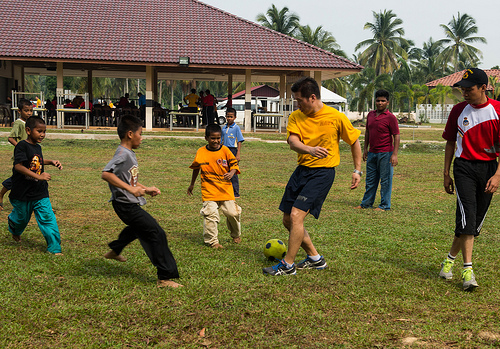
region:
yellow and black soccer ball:
[261, 235, 286, 265]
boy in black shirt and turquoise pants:
[11, 117, 70, 259]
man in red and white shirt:
[440, 68, 496, 298]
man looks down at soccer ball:
[434, 66, 498, 293]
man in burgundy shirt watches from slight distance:
[361, 89, 406, 211]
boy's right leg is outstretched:
[102, 109, 184, 290]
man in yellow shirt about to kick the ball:
[258, 70, 367, 283]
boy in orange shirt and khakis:
[191, 123, 246, 248]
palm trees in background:
[253, 4, 488, 111]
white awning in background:
[319, 81, 351, 106]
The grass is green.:
[241, 291, 282, 343]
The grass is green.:
[224, 265, 348, 345]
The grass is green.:
[248, 301, 370, 342]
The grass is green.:
[208, 294, 318, 342]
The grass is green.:
[255, 285, 409, 339]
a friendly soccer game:
[5, 26, 498, 310]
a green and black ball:
[230, 202, 332, 304]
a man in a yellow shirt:
[261, 67, 378, 304]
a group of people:
[5, 61, 257, 145]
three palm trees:
[259, 4, 495, 121]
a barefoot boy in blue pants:
[5, 106, 94, 288]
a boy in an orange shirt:
[164, 113, 270, 267]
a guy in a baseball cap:
[415, 47, 497, 306]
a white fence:
[402, 94, 466, 131]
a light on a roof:
[157, 33, 227, 93]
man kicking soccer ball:
[259, 75, 350, 278]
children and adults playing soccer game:
[14, 59, 496, 259]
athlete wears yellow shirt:
[276, 78, 351, 270]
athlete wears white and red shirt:
[441, 71, 499, 283]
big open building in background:
[0, 1, 351, 132]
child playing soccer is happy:
[194, 124, 241, 245]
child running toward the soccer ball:
[103, 119, 180, 286]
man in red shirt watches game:
[363, 90, 398, 201]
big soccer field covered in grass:
[0, 135, 495, 343]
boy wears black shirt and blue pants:
[11, 119, 63, 251]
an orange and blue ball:
[263, 236, 288, 263]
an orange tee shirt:
[286, 103, 362, 168]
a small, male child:
[185, 123, 242, 251]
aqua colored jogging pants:
[5, 191, 63, 253]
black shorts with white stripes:
[452, 153, 497, 235]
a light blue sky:
[326, 8, 351, 25]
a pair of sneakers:
[256, 253, 334, 276]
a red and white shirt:
[442, 93, 499, 163]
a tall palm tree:
[356, 8, 412, 113]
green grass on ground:
[200, 291, 344, 328]